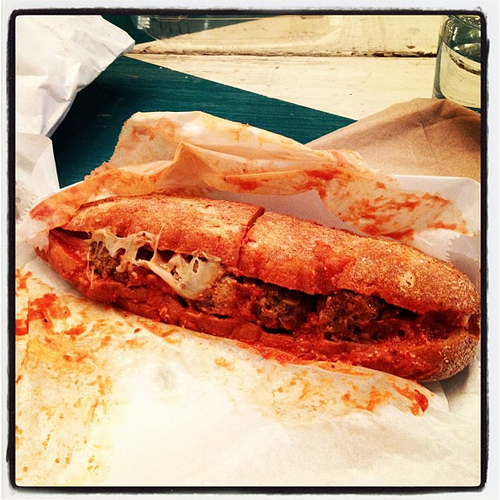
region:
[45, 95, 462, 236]
white paper stained with red sauce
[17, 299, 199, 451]
red sauce on paper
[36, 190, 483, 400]
the sandwich is cut in two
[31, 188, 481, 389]
two halfs of sandwich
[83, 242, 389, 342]
pieces of meat inside sandwich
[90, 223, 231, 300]
melted cheese over meat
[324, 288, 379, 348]
a piece of meat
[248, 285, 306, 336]
a piece of meat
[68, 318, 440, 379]
sandwich has red sauce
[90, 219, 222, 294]
melted cheese stuck to the sandwich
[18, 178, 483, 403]
a sub sandwich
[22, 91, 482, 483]
sauce stained onto a white paper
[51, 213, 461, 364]
meat and cheese stuffed into a sandwich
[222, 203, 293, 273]
a cut in the bread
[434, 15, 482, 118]
corner of a glass jar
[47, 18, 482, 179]
a wooden table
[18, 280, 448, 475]
sauce on a white paper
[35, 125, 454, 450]
this is a sandwich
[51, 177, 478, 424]
the sandwich has meatballs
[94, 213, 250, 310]
white cheese on sandwich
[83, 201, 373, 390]
red sauce on sandwich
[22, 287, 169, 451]
red sauce on parchment paper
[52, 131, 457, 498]
sandwich on top of paper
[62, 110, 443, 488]
parchment paper is white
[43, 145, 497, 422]
the sandwich is cut in half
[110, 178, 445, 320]
sandwich bun is brown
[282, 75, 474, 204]
paper bag next to sandwich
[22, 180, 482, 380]
red sauce over a sandwich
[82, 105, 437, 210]
paper is stained with sauce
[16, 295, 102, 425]
sauce over paper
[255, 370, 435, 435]
sauce over paper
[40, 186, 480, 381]
sandwich is cut in two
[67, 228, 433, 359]
meat inside the sandwich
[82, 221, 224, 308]
melted cheese on bread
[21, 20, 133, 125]
the paper is white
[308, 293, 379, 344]
a piece of meat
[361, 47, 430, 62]
Stains on the surface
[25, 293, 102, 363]
Orange stains on the surface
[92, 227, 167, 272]
A melted cheese hanging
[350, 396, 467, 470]
A white crumpled paper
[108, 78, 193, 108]
A green surface in the background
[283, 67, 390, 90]
A white table in the background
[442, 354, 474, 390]
Tip of the crusty bread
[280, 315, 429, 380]
Sauces overflowing on the bread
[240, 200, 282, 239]
Trace of slice on the bread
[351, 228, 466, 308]
Top of a long brown bread